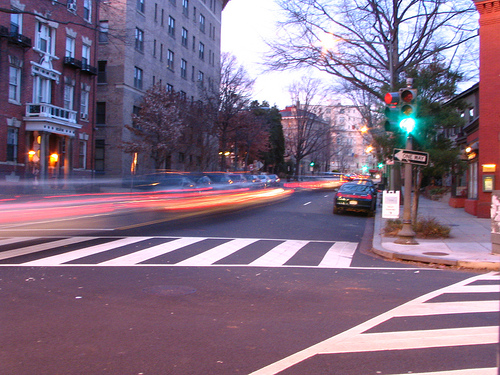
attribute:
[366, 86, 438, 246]
pole — metallic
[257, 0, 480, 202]
tree — bare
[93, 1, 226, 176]
building — brown 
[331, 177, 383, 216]
car — yellow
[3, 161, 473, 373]
street — paved, white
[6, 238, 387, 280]
stripes — thick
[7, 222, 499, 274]
crosswalk — white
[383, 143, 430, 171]
sign board — black, white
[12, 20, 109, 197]
building — brick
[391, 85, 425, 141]
traffic signal — bright green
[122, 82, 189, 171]
tree — flowing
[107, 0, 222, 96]
building — plain, brick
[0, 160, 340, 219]
flashes — red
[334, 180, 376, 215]
car — black